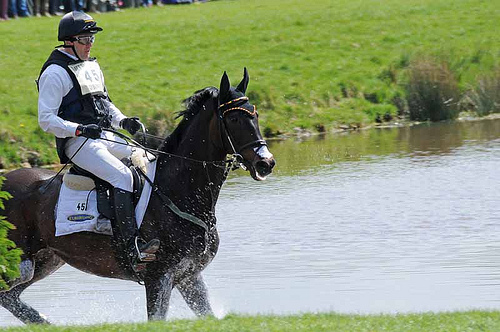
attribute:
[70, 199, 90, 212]
45 —  horse's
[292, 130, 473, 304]
water — body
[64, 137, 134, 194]
pants — white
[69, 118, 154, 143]
gloves — black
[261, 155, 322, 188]
hat — black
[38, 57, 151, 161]
vest — black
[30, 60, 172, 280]
man — wearing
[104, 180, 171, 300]
boots — black